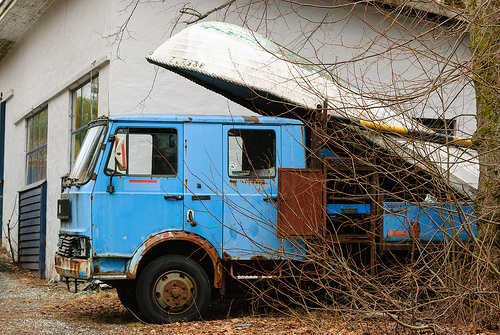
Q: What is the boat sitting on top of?
A: Truck.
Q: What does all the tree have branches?
A: No leaves on it.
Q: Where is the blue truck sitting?
A: On the ground.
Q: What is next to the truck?
A: The tree.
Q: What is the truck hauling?
A: Boat.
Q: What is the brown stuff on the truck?
A: Rust.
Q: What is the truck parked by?
A: Building.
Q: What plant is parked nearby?
A: Tree.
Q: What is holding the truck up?
A: Wheel.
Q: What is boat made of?
A: Metal.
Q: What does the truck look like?
A: Blue.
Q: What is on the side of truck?
A: Window.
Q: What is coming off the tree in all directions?
A: Limbs.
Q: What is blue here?
A: Cab of truck.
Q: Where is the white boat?
A: On back of blue truck.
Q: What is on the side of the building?
A: Two windows.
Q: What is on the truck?
A: White upside down boat.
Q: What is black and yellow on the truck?
A: Pole.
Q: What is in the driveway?
A: A blue rusted truck.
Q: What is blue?
A: A truck.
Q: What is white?
A: A boat.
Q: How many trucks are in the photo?
A: One.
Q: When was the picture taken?
A: Daytime.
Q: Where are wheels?
A: On the truck.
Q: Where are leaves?
A: On the ground.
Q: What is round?
A: A tire.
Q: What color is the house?
A: White.